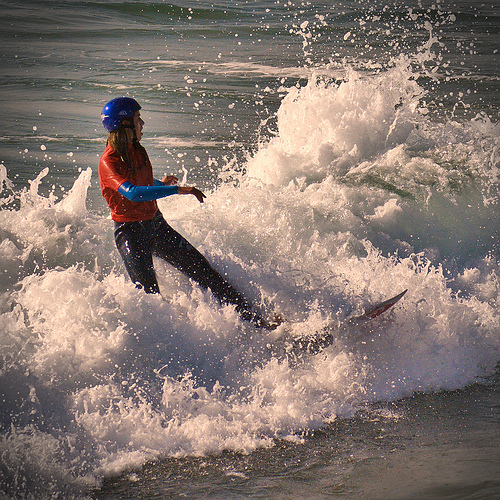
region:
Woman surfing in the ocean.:
[77, 80, 424, 369]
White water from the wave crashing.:
[25, 306, 187, 446]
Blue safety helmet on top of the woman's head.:
[97, 90, 147, 143]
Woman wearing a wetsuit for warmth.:
[91, 142, 264, 343]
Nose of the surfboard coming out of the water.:
[332, 275, 428, 325]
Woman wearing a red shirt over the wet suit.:
[92, 140, 164, 225]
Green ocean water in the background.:
[6, 5, 188, 67]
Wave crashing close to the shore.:
[252, 96, 494, 244]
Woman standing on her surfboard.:
[89, 91, 408, 348]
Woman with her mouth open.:
[91, 95, 153, 150]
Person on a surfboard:
[77, 73, 430, 387]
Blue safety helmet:
[88, 88, 143, 135]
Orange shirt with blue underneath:
[80, 131, 199, 240]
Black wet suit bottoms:
[108, 216, 278, 348]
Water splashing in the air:
[253, 19, 488, 216]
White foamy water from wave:
[6, 173, 471, 452]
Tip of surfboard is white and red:
[340, 276, 400, 341]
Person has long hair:
[88, 84, 165, 199]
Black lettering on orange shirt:
[128, 151, 156, 178]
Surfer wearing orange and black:
[88, 81, 295, 344]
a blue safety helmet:
[101, 97, 141, 130]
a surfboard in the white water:
[280, 290, 409, 362]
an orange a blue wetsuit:
[99, 138, 178, 223]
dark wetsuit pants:
[115, 220, 282, 342]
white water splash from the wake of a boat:
[407, 23, 498, 388]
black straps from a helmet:
[122, 117, 140, 151]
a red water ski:
[280, 289, 407, 360]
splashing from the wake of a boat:
[290, 0, 499, 425]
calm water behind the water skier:
[0, 0, 272, 92]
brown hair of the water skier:
[105, 131, 134, 168]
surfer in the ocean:
[86, 85, 308, 354]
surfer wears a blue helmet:
[86, 83, 288, 348]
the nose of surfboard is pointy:
[121, 286, 421, 390]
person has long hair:
[84, 83, 184, 203]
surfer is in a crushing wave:
[10, 58, 495, 458]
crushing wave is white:
[228, 52, 498, 398]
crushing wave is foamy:
[214, 74, 496, 396]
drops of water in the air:
[193, 2, 494, 59]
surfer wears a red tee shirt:
[86, 85, 282, 345]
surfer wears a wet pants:
[62, 83, 301, 345]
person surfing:
[69, 77, 280, 338]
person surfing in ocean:
[76, 97, 274, 349]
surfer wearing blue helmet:
[87, 94, 141, 127]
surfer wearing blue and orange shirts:
[93, 154, 171, 218]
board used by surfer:
[315, 277, 405, 354]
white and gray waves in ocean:
[19, 361, 474, 495]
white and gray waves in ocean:
[14, 15, 93, 425]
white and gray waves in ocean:
[26, 12, 477, 86]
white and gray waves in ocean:
[150, 14, 467, 158]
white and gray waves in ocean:
[238, 140, 485, 270]